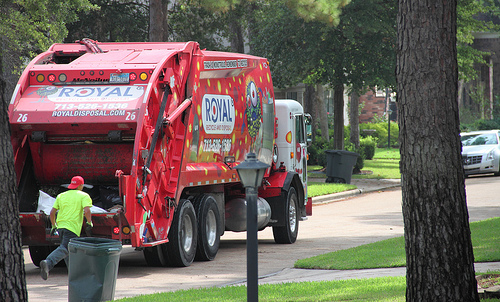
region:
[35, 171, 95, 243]
man wearing hat backwards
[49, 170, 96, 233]
man wearing green shirt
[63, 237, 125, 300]
garbage can on the sidewalk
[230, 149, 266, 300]
streetlamp on the sidewalk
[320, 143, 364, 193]
black dumpster on the lawn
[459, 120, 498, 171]
white car parked on side of road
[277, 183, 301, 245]
black tire on the truck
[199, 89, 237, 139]
royal sign on side of the truck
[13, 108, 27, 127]
number 26 on back of truck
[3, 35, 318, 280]
a red trash truck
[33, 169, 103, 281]
man following a trash truck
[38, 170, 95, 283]
man is wearing a red baseball cap back to front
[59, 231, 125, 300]
dark grey trash can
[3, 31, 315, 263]
trash truck is heavily decorated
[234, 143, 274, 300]
short street lamp in the foreground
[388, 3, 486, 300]
tall trunk of a tree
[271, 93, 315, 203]
cab of a trash truck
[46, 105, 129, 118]
website of the trash disposal company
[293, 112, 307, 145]
window on the side of a trash truck cab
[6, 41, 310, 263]
trash truck driving down the road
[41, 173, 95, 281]
man throwing trash in truck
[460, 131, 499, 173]
parked car on road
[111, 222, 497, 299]
bright green grass in yards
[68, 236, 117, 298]
trash can by the road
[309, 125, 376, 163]
bushes separating yards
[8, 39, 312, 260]
trash truck is painted red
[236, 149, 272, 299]
light pole by driveway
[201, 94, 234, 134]
royal logo on side of truck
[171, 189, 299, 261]
large wheels on truck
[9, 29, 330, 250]
a garbage truck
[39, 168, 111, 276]
garbage man running behing garabge truck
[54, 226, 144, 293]
empty garbage can that has just been emptied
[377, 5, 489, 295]
large tree trunk in a yard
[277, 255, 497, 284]
a paved driveway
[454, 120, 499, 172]
cadillac sedan parked on the street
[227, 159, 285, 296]
a lamp post in a yard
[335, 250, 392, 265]
lush, manicured green lawn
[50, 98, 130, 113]
trash service's phone number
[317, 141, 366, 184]
garbage can on street corner waiting to be emptied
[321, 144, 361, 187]
green trash can with wheels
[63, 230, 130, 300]
trash can with a dent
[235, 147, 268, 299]
an outside black lamp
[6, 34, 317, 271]
a red garbage truck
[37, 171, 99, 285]
a man with a red hat running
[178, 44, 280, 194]
polka dots on side of truck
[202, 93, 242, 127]
the word royal in blue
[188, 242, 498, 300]
green grass on both sides of sidewalk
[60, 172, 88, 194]
person wearing there hat backwards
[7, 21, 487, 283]
garbage truck driving down the street